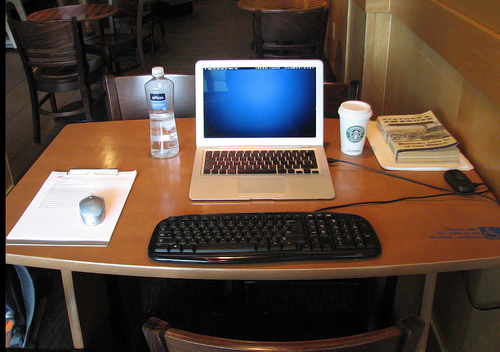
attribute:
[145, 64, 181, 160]
bottle — clear, plastic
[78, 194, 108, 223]
mouse — wireless, silver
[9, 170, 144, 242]
paper — white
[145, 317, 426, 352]
chair — brown, wooden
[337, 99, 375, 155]
cup — starbucks, white, styrofoam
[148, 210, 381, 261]
keyboard — black, rounded, plastic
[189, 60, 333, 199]
laptop — white, small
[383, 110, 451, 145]
cover — black, white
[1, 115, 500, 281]
table — light brown, wood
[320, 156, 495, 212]
wires — black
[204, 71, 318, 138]
screen — blue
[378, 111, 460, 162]
book — large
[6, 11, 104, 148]
chair — wooden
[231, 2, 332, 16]
table — round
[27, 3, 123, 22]
table — wood